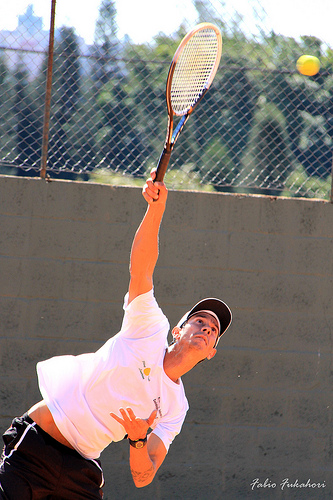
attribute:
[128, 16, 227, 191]
racket — black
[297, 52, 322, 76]
ball — yellow